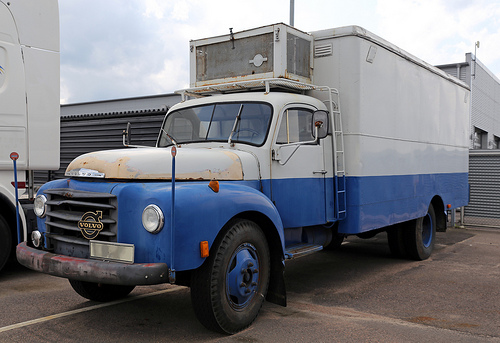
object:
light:
[139, 201, 164, 236]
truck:
[12, 23, 473, 337]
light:
[28, 189, 50, 217]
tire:
[189, 216, 273, 337]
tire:
[386, 204, 439, 263]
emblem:
[77, 209, 106, 240]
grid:
[40, 186, 120, 258]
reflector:
[199, 239, 211, 258]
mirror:
[309, 108, 330, 140]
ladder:
[324, 80, 351, 220]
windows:
[157, 99, 272, 148]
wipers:
[225, 99, 246, 144]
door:
[269, 101, 326, 228]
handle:
[307, 167, 328, 178]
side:
[250, 22, 471, 235]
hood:
[62, 146, 263, 183]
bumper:
[13, 241, 171, 287]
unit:
[184, 22, 312, 94]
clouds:
[55, 0, 499, 104]